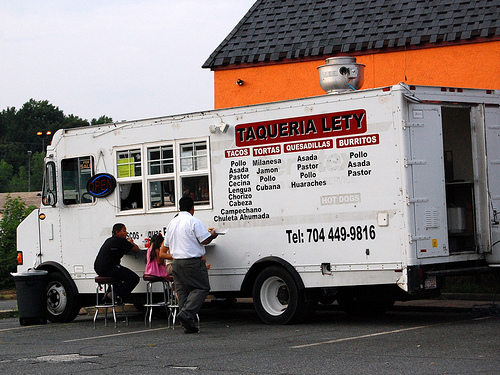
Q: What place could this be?
A: It is a parking lot.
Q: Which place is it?
A: It is a parking lot.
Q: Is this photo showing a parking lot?
A: Yes, it is showing a parking lot.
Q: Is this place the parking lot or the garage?
A: It is the parking lot.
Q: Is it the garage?
A: No, it is the parking lot.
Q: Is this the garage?
A: No, it is the parking lot.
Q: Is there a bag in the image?
A: No, there are no bags.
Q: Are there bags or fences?
A: No, there are no bags or fences.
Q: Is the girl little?
A: Yes, the girl is little.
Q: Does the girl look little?
A: Yes, the girl is little.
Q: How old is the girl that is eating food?
A: The girl is little.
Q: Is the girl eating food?
A: Yes, the girl is eating food.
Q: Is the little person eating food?
A: Yes, the girl is eating food.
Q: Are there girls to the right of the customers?
A: Yes, there is a girl to the right of the customers.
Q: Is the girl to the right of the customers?
A: Yes, the girl is to the right of the customers.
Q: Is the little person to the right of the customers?
A: Yes, the girl is to the right of the customers.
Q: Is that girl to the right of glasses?
A: No, the girl is to the right of the customers.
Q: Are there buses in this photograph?
A: No, there are no buses.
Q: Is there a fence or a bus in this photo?
A: No, there are no buses or fences.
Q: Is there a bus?
A: No, there are no buses.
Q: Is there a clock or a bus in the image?
A: No, there are no buses or clocks.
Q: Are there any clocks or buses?
A: No, there are no buses or clocks.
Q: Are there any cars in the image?
A: No, there are no cars.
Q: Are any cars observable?
A: No, there are no cars.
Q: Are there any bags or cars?
A: No, there are no cars or bags.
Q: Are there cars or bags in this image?
A: No, there are no cars or bags.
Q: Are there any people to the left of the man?
A: Yes, there are people to the left of the man.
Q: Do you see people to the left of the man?
A: Yes, there are people to the left of the man.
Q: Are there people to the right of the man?
A: No, the people are to the left of the man.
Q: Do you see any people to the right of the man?
A: No, the people are to the left of the man.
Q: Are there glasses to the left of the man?
A: No, there are people to the left of the man.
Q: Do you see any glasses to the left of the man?
A: No, there are people to the left of the man.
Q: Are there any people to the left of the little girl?
A: Yes, there are people to the left of the girl.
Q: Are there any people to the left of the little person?
A: Yes, there are people to the left of the girl.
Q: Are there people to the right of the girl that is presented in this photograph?
A: No, the people are to the left of the girl.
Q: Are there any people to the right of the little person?
A: No, the people are to the left of the girl.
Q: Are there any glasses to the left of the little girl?
A: No, there are people to the left of the girl.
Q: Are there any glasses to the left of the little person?
A: No, there are people to the left of the girl.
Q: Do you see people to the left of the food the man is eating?
A: Yes, there are people to the left of the food.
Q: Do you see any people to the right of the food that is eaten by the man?
A: No, the people are to the left of the food.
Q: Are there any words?
A: Yes, there are words.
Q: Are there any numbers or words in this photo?
A: Yes, there are words.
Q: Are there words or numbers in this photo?
A: Yes, there are words.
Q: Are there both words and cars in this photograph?
A: No, there are words but no cars.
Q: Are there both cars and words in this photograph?
A: No, there are words but no cars.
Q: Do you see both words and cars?
A: No, there are words but no cars.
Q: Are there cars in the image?
A: No, there are no cars.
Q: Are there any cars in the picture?
A: No, there are no cars.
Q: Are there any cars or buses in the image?
A: No, there are no cars or buses.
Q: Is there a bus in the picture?
A: No, there are no buses.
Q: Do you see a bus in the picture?
A: No, there are no buses.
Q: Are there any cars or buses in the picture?
A: No, there are no buses or cars.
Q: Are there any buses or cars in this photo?
A: No, there are no cars or buses.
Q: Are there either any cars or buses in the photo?
A: No, there are no cars or buses.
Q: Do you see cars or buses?
A: No, there are no cars or buses.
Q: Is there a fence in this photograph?
A: No, there are no fences.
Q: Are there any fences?
A: No, there are no fences.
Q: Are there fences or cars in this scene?
A: No, there are no fences or cars.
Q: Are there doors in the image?
A: Yes, there is a door.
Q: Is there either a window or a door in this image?
A: Yes, there is a door.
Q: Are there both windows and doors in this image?
A: Yes, there are both a door and a window.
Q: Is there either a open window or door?
A: Yes, there is an open door.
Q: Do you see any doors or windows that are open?
A: Yes, the door is open.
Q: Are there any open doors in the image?
A: Yes, there is an open door.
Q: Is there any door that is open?
A: Yes, there is a door that is open.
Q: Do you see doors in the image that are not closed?
A: Yes, there is a open door.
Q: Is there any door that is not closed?
A: Yes, there is a open door.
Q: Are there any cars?
A: No, there are no cars.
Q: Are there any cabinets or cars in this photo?
A: No, there are no cars or cabinets.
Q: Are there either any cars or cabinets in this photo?
A: No, there are no cars or cabinets.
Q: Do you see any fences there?
A: No, there are no fences.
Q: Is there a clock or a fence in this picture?
A: No, there are no fences or clocks.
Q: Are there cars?
A: No, there are no cars.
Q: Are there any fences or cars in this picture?
A: No, there are no cars or fences.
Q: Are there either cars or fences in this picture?
A: No, there are no cars or fences.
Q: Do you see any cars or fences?
A: No, there are no cars or fences.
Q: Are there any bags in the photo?
A: No, there are no bags.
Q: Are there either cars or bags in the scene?
A: No, there are no bags or cars.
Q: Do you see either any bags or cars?
A: No, there are no bags or cars.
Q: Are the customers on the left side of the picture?
A: Yes, the customers are on the left of the image.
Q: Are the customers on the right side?
A: No, the customers are on the left of the image.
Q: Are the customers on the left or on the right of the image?
A: The customers are on the left of the image.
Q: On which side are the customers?
A: The customers are on the left of the image.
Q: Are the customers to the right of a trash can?
A: Yes, the customers are to the right of a trash can.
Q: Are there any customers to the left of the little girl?
A: Yes, there are customers to the left of the girl.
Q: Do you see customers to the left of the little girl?
A: Yes, there are customers to the left of the girl.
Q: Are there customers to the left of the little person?
A: Yes, there are customers to the left of the girl.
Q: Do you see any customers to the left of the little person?
A: Yes, there are customers to the left of the girl.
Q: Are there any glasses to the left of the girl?
A: No, there are customers to the left of the girl.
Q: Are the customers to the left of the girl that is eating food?
A: Yes, the customers are to the left of the girl.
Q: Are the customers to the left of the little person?
A: Yes, the customers are to the left of the girl.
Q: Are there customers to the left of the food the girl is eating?
A: Yes, there are customers to the left of the food.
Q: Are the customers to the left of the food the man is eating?
A: Yes, the customers are to the left of the food.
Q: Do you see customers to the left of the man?
A: Yes, there are customers to the left of the man.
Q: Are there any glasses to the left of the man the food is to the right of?
A: No, there are customers to the left of the man.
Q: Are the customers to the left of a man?
A: Yes, the customers are to the left of a man.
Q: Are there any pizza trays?
A: No, there are no pizza trays.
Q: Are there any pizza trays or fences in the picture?
A: No, there are no pizza trays or fences.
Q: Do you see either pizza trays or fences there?
A: No, there are no pizza trays or fences.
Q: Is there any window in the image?
A: Yes, there is a window.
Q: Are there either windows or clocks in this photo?
A: Yes, there is a window.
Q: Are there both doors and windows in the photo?
A: Yes, there are both a window and a door.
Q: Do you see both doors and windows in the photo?
A: Yes, there are both a window and a door.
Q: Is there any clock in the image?
A: No, there are no clocks.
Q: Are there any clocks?
A: No, there are no clocks.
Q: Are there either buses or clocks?
A: No, there are no clocks or buses.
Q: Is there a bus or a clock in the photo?
A: No, there are no clocks or buses.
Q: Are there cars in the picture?
A: No, there are no cars.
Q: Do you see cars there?
A: No, there are no cars.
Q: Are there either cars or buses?
A: No, there are no cars or buses.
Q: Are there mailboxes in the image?
A: No, there are no mailboxes.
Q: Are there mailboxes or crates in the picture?
A: No, there are no mailboxes or crates.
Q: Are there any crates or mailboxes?
A: No, there are no mailboxes or crates.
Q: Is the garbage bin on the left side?
A: Yes, the garbage bin is on the left of the image.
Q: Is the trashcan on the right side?
A: No, the trashcan is on the left of the image.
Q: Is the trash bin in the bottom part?
A: Yes, the trash bin is in the bottom of the image.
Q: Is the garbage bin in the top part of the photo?
A: No, the garbage bin is in the bottom of the image.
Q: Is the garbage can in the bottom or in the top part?
A: The garbage can is in the bottom of the image.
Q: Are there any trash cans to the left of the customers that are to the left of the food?
A: Yes, there is a trash can to the left of the customers.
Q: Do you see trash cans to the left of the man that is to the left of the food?
A: Yes, there is a trash can to the left of the man.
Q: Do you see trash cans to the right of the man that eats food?
A: No, the trash can is to the left of the man.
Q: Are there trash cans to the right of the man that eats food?
A: No, the trash can is to the left of the man.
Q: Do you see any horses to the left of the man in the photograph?
A: No, there is a trash can to the left of the man.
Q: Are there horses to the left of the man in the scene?
A: No, there is a trash can to the left of the man.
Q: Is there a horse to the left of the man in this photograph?
A: No, there is a trash can to the left of the man.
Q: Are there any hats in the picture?
A: Yes, there is a hat.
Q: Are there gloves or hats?
A: Yes, there is a hat.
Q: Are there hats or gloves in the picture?
A: Yes, there is a hat.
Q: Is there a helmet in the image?
A: No, there are no helmets.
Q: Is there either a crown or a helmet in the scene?
A: No, there are no helmets or crowns.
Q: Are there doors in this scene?
A: Yes, there is a door.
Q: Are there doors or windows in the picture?
A: Yes, there is a door.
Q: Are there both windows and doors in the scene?
A: Yes, there are both a door and windows.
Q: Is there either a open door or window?
A: Yes, there is an open door.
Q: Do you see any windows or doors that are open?
A: Yes, the door is open.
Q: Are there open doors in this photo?
A: Yes, there is an open door.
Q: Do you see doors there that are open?
A: Yes, there is a door that is open.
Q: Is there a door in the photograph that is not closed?
A: Yes, there is a open door.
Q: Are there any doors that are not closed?
A: Yes, there is a open door.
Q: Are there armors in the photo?
A: No, there are no armors.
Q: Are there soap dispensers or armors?
A: No, there are no armors or soap dispensers.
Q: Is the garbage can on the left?
A: Yes, the garbage can is on the left of the image.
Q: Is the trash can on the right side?
A: No, the trash can is on the left of the image.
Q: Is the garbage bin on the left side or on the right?
A: The garbage bin is on the left of the image.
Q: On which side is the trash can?
A: The trash can is on the left of the image.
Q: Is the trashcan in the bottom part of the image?
A: Yes, the trashcan is in the bottom of the image.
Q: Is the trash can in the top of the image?
A: No, the trash can is in the bottom of the image.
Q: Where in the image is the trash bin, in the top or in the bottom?
A: The trash bin is in the bottom of the image.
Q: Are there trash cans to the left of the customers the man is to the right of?
A: Yes, there is a trash can to the left of the customers.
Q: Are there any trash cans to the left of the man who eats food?
A: Yes, there is a trash can to the left of the man.